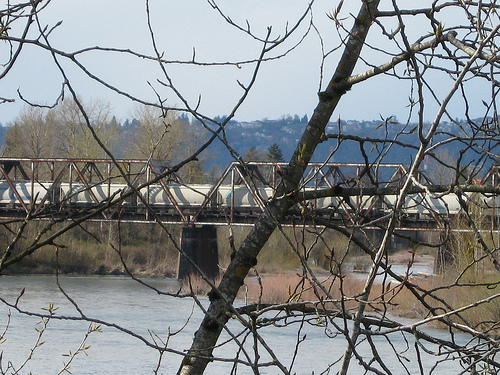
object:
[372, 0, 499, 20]
branch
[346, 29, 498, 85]
branch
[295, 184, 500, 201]
branch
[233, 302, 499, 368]
branch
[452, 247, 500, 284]
sticks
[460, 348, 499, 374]
sticks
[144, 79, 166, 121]
sticks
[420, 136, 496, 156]
sticks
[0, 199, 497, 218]
train tracks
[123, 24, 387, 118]
clouds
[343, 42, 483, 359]
branch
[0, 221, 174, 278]
vegetation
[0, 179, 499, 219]
train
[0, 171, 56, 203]
car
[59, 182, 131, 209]
car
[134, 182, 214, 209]
car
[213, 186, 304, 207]
car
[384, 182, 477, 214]
car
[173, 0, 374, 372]
trunk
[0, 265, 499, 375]
stream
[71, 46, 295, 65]
twig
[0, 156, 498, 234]
fence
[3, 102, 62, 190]
tree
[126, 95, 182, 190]
tree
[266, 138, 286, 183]
tree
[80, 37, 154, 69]
branch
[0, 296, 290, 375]
branch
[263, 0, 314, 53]
branch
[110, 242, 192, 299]
branch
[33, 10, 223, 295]
branch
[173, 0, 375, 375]
branch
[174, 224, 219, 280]
base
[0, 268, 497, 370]
water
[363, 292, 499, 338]
tree branch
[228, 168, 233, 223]
girding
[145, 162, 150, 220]
girding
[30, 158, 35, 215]
girding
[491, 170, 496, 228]
girding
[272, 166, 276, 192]
girding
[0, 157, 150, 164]
railing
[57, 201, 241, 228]
bridge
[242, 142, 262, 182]
tree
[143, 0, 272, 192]
branch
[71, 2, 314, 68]
branch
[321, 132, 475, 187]
branch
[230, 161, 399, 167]
metal railing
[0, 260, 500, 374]
river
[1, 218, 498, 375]
bank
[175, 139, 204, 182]
tree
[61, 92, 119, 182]
tree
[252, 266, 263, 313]
sticks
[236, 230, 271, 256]
bark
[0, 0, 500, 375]
photo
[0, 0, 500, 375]
autum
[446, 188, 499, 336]
bush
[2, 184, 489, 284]
bridge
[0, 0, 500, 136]
sky